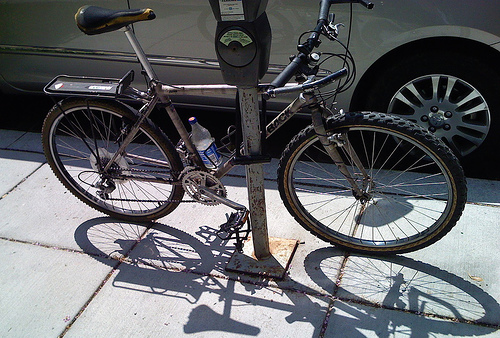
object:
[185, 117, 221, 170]
bottle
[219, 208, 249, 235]
pedal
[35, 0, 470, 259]
bicycle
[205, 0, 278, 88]
parking meter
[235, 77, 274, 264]
pole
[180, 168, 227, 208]
gear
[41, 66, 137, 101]
rack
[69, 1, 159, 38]
seat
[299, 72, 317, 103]
brake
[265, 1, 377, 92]
handle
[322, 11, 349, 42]
brake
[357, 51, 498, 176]
wheel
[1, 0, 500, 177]
car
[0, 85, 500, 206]
shadow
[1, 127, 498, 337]
sidewalk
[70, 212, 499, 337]
shadow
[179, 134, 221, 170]
drink holder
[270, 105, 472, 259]
front wheel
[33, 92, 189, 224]
rear wheel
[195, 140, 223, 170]
water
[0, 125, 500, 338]
ground